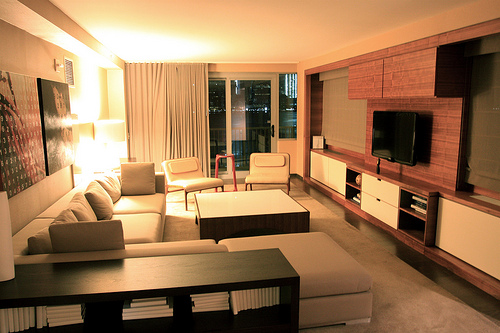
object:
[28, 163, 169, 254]
couch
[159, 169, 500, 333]
floor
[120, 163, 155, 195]
pillows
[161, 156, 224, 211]
chairs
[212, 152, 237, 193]
table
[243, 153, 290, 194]
chairs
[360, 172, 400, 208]
drawers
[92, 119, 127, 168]
lamp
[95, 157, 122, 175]
table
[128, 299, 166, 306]
books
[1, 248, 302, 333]
shelf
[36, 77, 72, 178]
painting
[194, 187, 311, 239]
coffee table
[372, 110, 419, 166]
television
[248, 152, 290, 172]
back rest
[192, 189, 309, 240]
ottoman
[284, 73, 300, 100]
lights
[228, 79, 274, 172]
window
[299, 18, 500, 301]
wall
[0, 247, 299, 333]
cabinet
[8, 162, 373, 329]
chair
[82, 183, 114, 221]
pillow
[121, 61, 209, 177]
curtains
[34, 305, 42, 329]
books